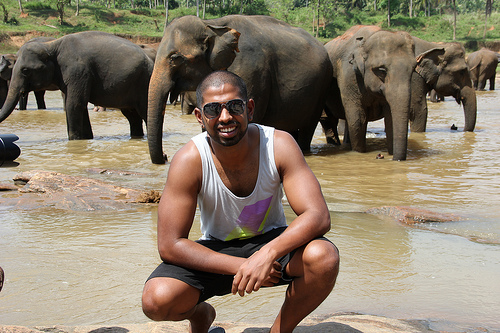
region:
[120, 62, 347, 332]
a man squatting down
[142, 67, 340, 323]
a man in a white tank top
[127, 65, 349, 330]
a man wearing black shorts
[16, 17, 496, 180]
a herd of elephants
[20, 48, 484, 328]
a lake of murky water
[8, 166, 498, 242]
large brown rocks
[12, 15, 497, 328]
a bath hole for elephants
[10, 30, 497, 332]
a watering hole for animals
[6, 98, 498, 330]
brown cloudy water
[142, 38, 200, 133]
dirt on the elephant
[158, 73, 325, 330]
this is a man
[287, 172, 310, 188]
the man is light skinned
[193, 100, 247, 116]
this is a spectacle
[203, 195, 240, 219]
this is a vest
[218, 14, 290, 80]
this is an elephant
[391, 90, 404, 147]
this is the trunk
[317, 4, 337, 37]
this is a tree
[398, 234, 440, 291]
this is a river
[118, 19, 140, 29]
this is a grass area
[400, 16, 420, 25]
the tree has green leaves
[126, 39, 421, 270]
the man is posing for a picture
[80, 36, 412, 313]
the man wears sunglasses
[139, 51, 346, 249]
the man wears a white shirt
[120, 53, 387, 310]
the man has black shorts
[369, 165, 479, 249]
the water is brown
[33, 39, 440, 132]
these are asian elephants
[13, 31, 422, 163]
three elephants in this box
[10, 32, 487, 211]
the elephants are in the water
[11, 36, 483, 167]
there are four elephants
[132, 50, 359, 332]
man squatting on river edge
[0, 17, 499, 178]
elephants wading in the water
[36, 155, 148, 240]
ripples in brown water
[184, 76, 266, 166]
young man wearing sunglasses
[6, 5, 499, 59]
trees growing on the river bank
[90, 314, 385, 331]
the man's shadow on the ground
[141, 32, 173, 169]
brown and gray elephant's trunk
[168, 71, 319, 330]
ban in black shorts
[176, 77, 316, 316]
man in white tank top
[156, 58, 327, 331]
this is a man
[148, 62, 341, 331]
the man is squatting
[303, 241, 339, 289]
this is the knee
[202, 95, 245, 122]
the man is wearing goggles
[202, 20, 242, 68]
the ear is big in size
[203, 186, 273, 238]
the man is wearing a vest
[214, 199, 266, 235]
the vest is white in color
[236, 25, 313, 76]
the elephant is black in color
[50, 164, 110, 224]
the water is brown in color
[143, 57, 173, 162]
this is the trunk